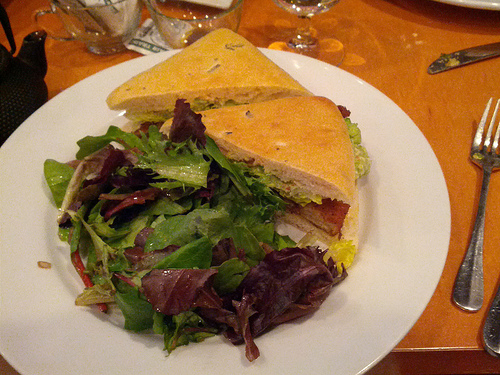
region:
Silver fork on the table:
[452, 94, 498, 324]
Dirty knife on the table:
[421, 36, 499, 77]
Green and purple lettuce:
[89, 156, 271, 332]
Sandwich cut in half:
[104, 43, 361, 235]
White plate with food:
[7, 53, 453, 373]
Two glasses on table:
[33, 3, 239, 51]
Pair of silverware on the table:
[452, 75, 499, 362]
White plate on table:
[1, 45, 446, 373]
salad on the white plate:
[76, 157, 267, 335]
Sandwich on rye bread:
[114, 92, 357, 188]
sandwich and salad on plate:
[31, 23, 368, 373]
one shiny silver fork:
[448, 85, 498, 315]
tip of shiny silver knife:
[424, 30, 496, 77]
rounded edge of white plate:
[365, 78, 454, 370]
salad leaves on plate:
[43, 173, 298, 371]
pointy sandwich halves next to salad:
[111, 23, 372, 267]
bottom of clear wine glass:
[269, 15, 349, 65]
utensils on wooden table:
[363, 29, 498, 360]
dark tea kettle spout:
[15, 22, 51, 84]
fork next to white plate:
[393, 88, 499, 316]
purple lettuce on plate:
[265, 252, 338, 320]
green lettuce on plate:
[165, 155, 230, 241]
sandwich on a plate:
[295, 95, 371, 221]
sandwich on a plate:
[210, 25, 292, 95]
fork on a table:
[450, 145, 495, 300]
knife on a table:
[420, 32, 490, 82]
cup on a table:
[62, 0, 123, 55]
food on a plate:
[45, 40, 375, 346]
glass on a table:
[275, 0, 357, 50]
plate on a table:
[401, 101, 448, 328]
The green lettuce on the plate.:
[51, 150, 316, 320]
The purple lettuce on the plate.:
[55, 131, 327, 326]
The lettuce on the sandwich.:
[220, 102, 377, 197]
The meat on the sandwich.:
[262, 178, 349, 233]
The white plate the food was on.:
[6, 32, 431, 374]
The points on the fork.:
[470, 92, 497, 168]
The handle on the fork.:
[458, 170, 486, 331]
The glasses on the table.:
[36, 0, 333, 52]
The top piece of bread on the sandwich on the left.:
[97, 28, 306, 100]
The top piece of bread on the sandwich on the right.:
[165, 95, 355, 197]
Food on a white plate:
[0, 30, 450, 373]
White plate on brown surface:
[3, 45, 447, 373]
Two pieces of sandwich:
[105, 27, 368, 248]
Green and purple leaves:
[45, 126, 343, 362]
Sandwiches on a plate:
[107, 26, 357, 243]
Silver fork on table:
[455, 93, 498, 311]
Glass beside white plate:
[147, 0, 242, 50]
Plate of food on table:
[0, 30, 453, 372]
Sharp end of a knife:
[429, 40, 497, 77]